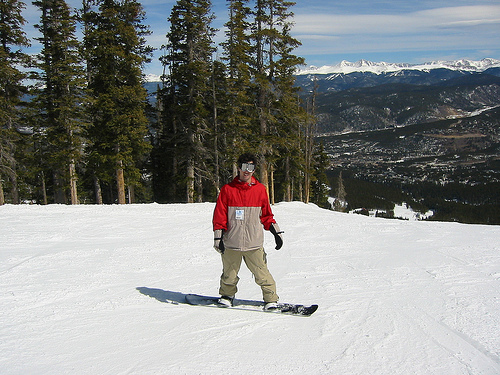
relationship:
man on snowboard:
[216, 156, 284, 303] [186, 284, 327, 336]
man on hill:
[216, 156, 284, 303] [317, 223, 428, 320]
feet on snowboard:
[218, 287, 284, 305] [186, 284, 327, 336]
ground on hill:
[38, 229, 116, 245] [317, 223, 428, 320]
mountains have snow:
[340, 53, 494, 104] [318, 68, 326, 76]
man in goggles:
[216, 156, 284, 303] [236, 160, 262, 173]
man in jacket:
[216, 156, 284, 303] [217, 177, 275, 252]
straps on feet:
[215, 294, 248, 311] [218, 287, 284, 305]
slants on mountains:
[459, 105, 487, 134] [340, 53, 494, 104]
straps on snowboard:
[215, 294, 248, 311] [186, 284, 327, 336]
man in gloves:
[216, 156, 284, 303] [265, 215, 287, 257]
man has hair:
[216, 156, 284, 303] [240, 152, 273, 163]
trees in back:
[174, 13, 308, 155] [312, 4, 339, 32]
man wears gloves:
[216, 156, 284, 303] [265, 215, 287, 257]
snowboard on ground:
[186, 284, 327, 336] [38, 229, 116, 245]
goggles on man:
[236, 160, 262, 173] [216, 156, 284, 303]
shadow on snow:
[116, 272, 181, 320] [318, 68, 326, 76]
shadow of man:
[116, 272, 181, 320] [216, 156, 284, 303]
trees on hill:
[174, 13, 308, 155] [317, 223, 428, 320]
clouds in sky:
[368, 6, 413, 39] [319, 37, 393, 75]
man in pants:
[216, 156, 284, 303] [217, 248, 297, 309]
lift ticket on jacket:
[229, 210, 247, 228] [217, 177, 275, 252]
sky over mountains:
[319, 37, 393, 75] [340, 53, 494, 104]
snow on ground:
[318, 68, 326, 76] [38, 229, 116, 245]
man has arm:
[216, 156, 284, 303] [259, 185, 272, 225]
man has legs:
[216, 156, 284, 303] [227, 240, 274, 299]